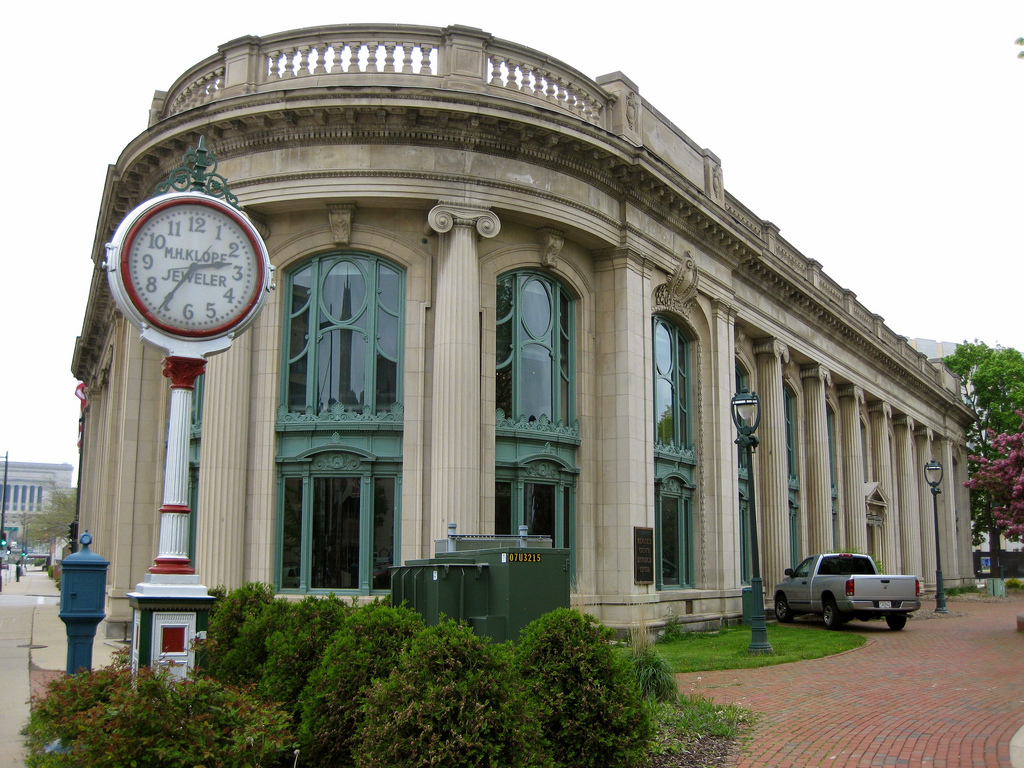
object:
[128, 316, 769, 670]
building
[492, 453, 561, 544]
window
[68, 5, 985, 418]
building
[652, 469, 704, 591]
window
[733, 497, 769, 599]
window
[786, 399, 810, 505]
window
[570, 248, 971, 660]
building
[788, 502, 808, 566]
window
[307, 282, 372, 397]
frame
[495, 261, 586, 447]
window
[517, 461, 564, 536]
frame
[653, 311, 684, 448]
frame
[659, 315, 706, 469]
window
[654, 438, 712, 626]
window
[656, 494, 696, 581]
frame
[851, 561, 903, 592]
grey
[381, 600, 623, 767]
bush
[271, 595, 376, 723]
bush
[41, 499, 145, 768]
post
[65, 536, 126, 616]
top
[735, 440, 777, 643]
pole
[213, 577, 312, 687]
shrubs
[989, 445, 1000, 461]
flowers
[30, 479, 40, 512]
pillars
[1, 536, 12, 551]
lights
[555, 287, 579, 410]
frame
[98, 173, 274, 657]
standing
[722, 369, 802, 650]
green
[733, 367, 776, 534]
light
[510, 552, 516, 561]
yellow number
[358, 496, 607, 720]
box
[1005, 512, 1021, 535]
lavender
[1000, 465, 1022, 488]
flowers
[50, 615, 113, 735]
pole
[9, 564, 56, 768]
sidewalk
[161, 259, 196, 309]
black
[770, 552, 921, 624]
truck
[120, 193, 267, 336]
clock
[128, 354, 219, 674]
pole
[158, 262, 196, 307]
hands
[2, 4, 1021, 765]
city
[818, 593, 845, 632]
wheel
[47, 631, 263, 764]
shrubs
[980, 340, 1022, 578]
trees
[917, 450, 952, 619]
street light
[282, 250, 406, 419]
window